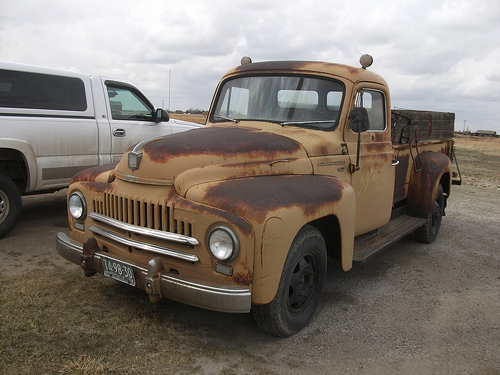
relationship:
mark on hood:
[132, 125, 306, 158] [102, 121, 315, 185]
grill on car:
[92, 192, 193, 267] [56, 54, 461, 339]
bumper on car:
[49, 233, 263, 325] [49, 44, 465, 336]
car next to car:
[0, 61, 205, 238] [56, 54, 461, 339]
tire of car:
[251, 224, 329, 338] [56, 54, 461, 339]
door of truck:
[341, 81, 395, 236] [67, 51, 459, 310]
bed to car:
[370, 75, 485, 225] [56, 54, 461, 339]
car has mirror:
[56, 54, 461, 339] [347, 105, 369, 172]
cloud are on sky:
[0, 0, 499, 122] [0, 0, 499, 134]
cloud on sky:
[0, 0, 499, 122] [0, 0, 499, 134]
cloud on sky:
[0, 0, 185, 85] [0, 0, 499, 134]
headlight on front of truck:
[206, 225, 241, 264] [60, 34, 478, 320]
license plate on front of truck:
[101, 257, 136, 287] [65, 47, 430, 328]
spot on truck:
[203, 169, 343, 218] [58, 61, 465, 336]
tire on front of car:
[282, 225, 336, 326] [56, 54, 461, 339]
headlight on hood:
[206, 225, 241, 264] [65, 125, 334, 274]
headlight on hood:
[65, 190, 87, 221] [65, 125, 334, 274]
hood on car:
[65, 125, 334, 274] [56, 54, 461, 339]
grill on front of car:
[74, 185, 205, 252] [56, 54, 461, 339]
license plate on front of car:
[101, 257, 136, 287] [49, 44, 465, 336]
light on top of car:
[355, 51, 379, 69] [38, 11, 498, 323]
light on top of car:
[235, 55, 255, 69] [38, 11, 498, 323]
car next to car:
[49, 44, 465, 336] [0, 66, 204, 233]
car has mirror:
[49, 44, 465, 336] [345, 104, 372, 171]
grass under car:
[4, 269, 218, 374] [49, 44, 465, 336]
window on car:
[1, 69, 91, 112] [2, 53, 157, 187]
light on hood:
[123, 149, 141, 174] [112, 124, 317, 187]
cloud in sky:
[0, 0, 499, 122] [98, 0, 454, 89]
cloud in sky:
[0, 0, 499, 122] [4, 5, 482, 118]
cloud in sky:
[0, 0, 499, 122] [1, 2, 496, 106]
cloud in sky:
[0, 0, 499, 122] [400, 19, 495, 71]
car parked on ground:
[56, 54, 461, 339] [3, 159, 498, 370]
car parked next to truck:
[0, 61, 205, 238] [58, 61, 465, 336]